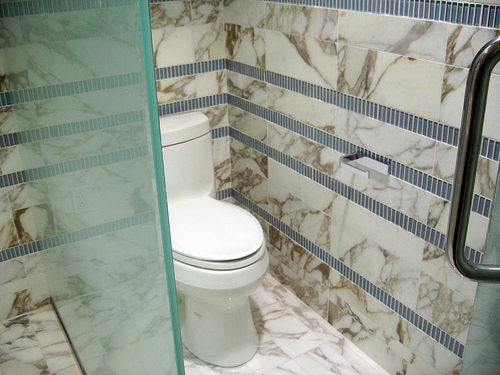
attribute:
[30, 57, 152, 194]
walls — marble, glass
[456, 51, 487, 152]
handle — chrome, metal, silver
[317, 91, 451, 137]
stripes — blue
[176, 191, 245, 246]
seat — down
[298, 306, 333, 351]
floor — marble, tiles, tile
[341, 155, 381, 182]
holder — steel, chrome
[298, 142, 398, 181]
paper — toilet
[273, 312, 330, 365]
tile — blue, white, tan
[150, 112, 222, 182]
tank — against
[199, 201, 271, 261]
cover — top, down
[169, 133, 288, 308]
toilet — white, clean, porcelain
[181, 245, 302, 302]
bowl — porcelain, shiny, ceramic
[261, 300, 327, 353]
tiles — marble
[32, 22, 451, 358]
bathroom — small, here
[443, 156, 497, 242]
bar — handicapped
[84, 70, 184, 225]
glass — divider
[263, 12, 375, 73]
marble — brown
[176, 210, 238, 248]
lid — plastic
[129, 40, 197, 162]
divider — glass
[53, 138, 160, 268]
door — glass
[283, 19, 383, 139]
wall — marble